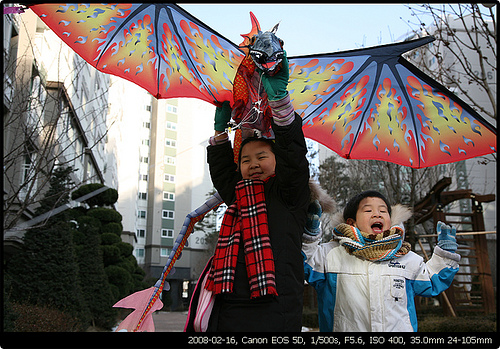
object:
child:
[204, 47, 311, 333]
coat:
[204, 112, 307, 328]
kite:
[20, 0, 497, 164]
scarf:
[199, 175, 284, 301]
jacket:
[189, 130, 314, 323]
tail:
[113, 166, 218, 332]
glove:
[212, 96, 232, 139]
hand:
[215, 99, 232, 126]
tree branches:
[410, 10, 500, 100]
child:
[300, 188, 461, 339]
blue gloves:
[436, 214, 457, 253]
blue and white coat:
[300, 224, 470, 332]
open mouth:
[367, 220, 383, 237]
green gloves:
[259, 53, 290, 102]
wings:
[270, 32, 498, 172]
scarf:
[326, 223, 415, 258]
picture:
[184, 334, 499, 345]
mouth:
[368, 223, 384, 231]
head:
[241, 25, 288, 66]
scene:
[38, 40, 480, 251]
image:
[114, 112, 423, 181]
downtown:
[442, 130, 499, 240]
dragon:
[208, 18, 287, 146]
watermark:
[180, 333, 494, 347]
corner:
[488, 334, 500, 348]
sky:
[192, 4, 420, 52]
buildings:
[114, 93, 210, 310]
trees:
[5, 35, 63, 226]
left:
[12, 188, 26, 207]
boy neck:
[338, 232, 413, 255]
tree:
[403, 8, 498, 124]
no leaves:
[439, 40, 454, 48]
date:
[183, 331, 238, 344]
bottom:
[137, 330, 151, 349]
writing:
[394, 276, 405, 292]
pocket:
[385, 267, 409, 303]